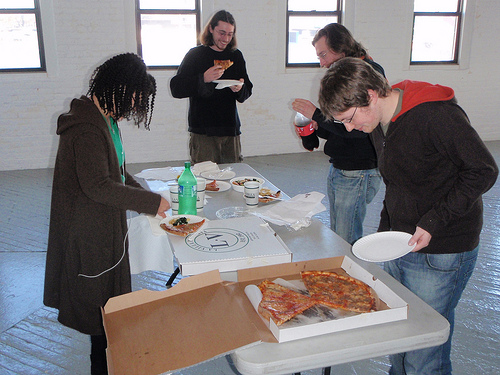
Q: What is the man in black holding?
A: Pizza.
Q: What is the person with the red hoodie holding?
A: A plate.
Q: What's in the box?
A: Pizza.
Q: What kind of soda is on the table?
A: Sprite.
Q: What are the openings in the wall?
A: Windows.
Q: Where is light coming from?
A: Windows.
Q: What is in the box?
A: Pizza.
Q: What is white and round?
A: Paper plates.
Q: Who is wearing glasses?
A: Person on right.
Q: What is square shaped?
A: Pizza boxes.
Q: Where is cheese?
A: On the pizza.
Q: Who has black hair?
A: Person on left.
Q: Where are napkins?
A: On the table.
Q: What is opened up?
A: Pizza box.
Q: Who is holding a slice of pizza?
A: Man at end of the table.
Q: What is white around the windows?
A: Wall.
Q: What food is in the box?
A: Pizza.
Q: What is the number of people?
A: 4.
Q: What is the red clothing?
A: Hood on jacket.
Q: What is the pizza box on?
A: Table.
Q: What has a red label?
A: Soda bottle.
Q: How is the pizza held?
A: In a hand.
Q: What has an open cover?
A: Pizza box.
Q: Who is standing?
A: All four people.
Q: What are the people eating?
A: Pizza.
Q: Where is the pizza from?
A: L V.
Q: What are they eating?
A: Pizza.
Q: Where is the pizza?
A: On the table.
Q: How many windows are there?
A: Four.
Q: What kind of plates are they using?
A: Paper plates.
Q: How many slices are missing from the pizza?
A: Three.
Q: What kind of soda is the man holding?
A: Coca Cola.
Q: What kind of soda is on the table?
A: Sprite.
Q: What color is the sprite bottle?
A: Green.